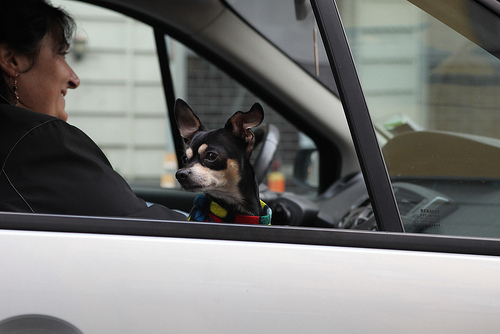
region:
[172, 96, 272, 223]
the dog in the car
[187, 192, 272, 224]
the fabric on the dog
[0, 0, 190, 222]
the woman sitting in the car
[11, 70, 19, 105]
the earrings in the woman's ear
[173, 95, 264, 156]
the ears on the dog's head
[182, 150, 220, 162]
the eyes on the dog's head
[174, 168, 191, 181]
the nose on the dog's face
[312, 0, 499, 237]
the glass window next to the dog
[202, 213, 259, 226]
the red coloring on the dog's clothes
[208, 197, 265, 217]
the yellow parts on the dog's clothes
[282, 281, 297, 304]
edge of a door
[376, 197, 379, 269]
part of a window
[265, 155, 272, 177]
part of a wheel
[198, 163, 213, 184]
face of a dog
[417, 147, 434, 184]
part of a window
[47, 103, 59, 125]
face of a woman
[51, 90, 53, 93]
part of a cheek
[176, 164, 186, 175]
Dog has black nose.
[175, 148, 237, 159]
Dog has dark eyes.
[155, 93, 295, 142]
Dog has black ears.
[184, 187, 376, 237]
Dog has colorful clothes on.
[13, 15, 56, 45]
Person has dark hair.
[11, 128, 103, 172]
Person wearing dark coat.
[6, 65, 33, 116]
Person wearing dangle earring.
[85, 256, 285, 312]
Person in light colored car.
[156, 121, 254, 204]
Dog is looking out window.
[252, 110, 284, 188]
Black steering wheel on car.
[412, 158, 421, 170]
part of a window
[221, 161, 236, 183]
head of a dog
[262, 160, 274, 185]
part of a wheel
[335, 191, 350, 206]
part of a board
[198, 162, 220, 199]
head of a dog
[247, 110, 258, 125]
ear of a dog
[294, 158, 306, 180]
part of a mirror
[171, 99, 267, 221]
black and brown dog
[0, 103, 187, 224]
black polyester spring jacket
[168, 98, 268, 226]
dog sitting at window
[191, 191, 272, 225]
polka dot dog sweater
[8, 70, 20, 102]
god dangle earring on ear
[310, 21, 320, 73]
air freshener on car mirror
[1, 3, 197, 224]
woman driving in car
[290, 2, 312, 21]
rear view mirror in car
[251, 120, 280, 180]
steering wheel in car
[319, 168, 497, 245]
dash in car